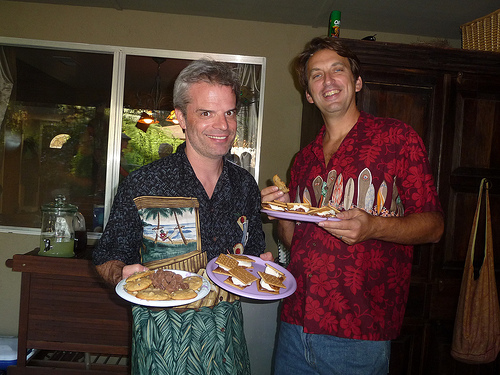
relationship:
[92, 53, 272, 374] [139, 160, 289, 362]
guy wearing shirt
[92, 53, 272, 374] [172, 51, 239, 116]
guy with gray silver hair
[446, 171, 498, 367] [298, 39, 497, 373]
bag hangs cupboard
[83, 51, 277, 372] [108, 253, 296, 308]
guy holding food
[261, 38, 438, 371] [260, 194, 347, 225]
guy holding food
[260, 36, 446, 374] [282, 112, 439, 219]
guy wearing red shirt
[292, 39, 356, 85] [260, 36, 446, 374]
hair on guy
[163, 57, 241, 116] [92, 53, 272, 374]
silver hair on guy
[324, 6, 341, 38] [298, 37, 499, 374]
spray on cupboard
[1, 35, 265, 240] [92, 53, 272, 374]
window behind guy